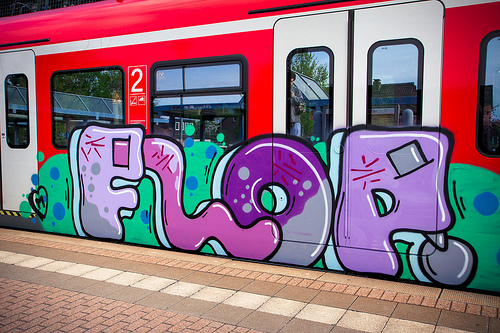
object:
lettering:
[222, 133, 333, 266]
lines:
[0, 37, 51, 47]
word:
[65, 123, 456, 280]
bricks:
[120, 309, 151, 323]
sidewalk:
[0, 227, 499, 332]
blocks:
[188, 285, 238, 303]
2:
[130, 68, 144, 93]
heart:
[27, 185, 49, 216]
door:
[344, 0, 441, 256]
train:
[0, 0, 500, 295]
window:
[369, 41, 422, 128]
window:
[287, 49, 330, 167]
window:
[50, 69, 123, 148]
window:
[474, 30, 498, 156]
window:
[151, 60, 249, 149]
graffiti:
[332, 128, 454, 276]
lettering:
[335, 126, 453, 275]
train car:
[3, 0, 498, 296]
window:
[5, 73, 31, 149]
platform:
[0, 229, 499, 331]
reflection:
[481, 76, 499, 153]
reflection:
[365, 77, 419, 130]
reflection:
[287, 51, 333, 147]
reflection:
[153, 60, 247, 150]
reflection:
[47, 69, 120, 149]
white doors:
[1, 50, 38, 214]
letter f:
[77, 124, 147, 239]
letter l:
[142, 137, 289, 259]